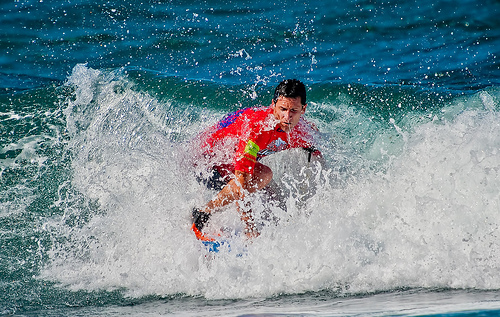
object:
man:
[190, 79, 331, 239]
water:
[0, 0, 500, 317]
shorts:
[192, 167, 236, 193]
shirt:
[186, 107, 329, 175]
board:
[192, 221, 246, 261]